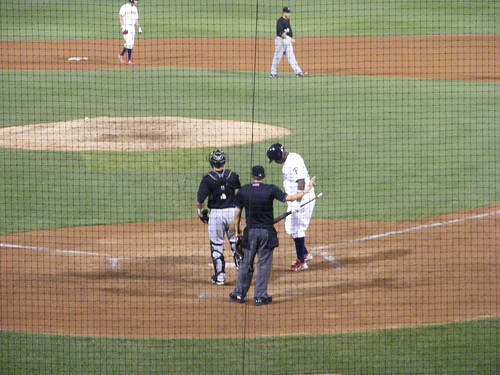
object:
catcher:
[197, 147, 245, 285]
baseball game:
[10, 10, 487, 360]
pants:
[206, 206, 238, 286]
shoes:
[288, 259, 309, 271]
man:
[230, 162, 318, 306]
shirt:
[235, 182, 285, 227]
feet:
[211, 275, 225, 285]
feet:
[295, 70, 308, 77]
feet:
[270, 74, 279, 79]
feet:
[254, 295, 273, 306]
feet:
[228, 291, 245, 303]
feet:
[211, 276, 225, 286]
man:
[266, 142, 321, 273]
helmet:
[266, 143, 285, 166]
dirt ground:
[331, 229, 476, 328]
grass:
[0, 1, 497, 373]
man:
[116, 0, 142, 66]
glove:
[121, 25, 129, 34]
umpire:
[232, 181, 287, 300]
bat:
[272, 192, 325, 224]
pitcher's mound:
[185, 140, 322, 315]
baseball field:
[42, 56, 483, 358]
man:
[196, 149, 243, 286]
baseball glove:
[197, 208, 209, 225]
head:
[266, 143, 287, 165]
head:
[282, 6, 290, 14]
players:
[182, 121, 342, 301]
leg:
[232, 245, 257, 294]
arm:
[291, 158, 305, 212]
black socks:
[292, 236, 304, 263]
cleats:
[285, 244, 318, 280]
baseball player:
[266, 142, 317, 272]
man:
[270, 4, 308, 79]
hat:
[282, 6, 292, 14]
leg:
[208, 225, 227, 282]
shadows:
[300, 244, 405, 305]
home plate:
[209, 239, 224, 283]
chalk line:
[316, 209, 498, 249]